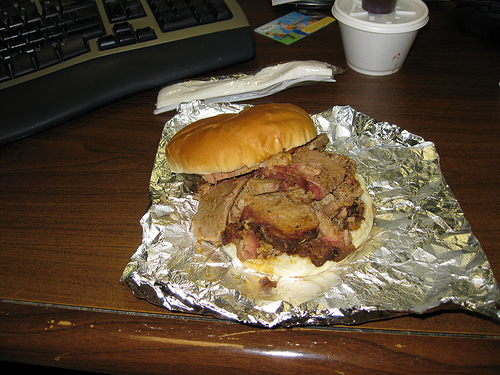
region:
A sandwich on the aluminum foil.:
[158, 108, 412, 295]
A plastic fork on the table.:
[165, 56, 360, 104]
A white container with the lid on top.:
[331, 6, 448, 75]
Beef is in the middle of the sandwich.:
[194, 168, 356, 241]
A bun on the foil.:
[153, 98, 340, 158]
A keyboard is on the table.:
[23, 11, 271, 78]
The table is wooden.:
[33, 180, 203, 362]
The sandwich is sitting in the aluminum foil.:
[168, 161, 445, 314]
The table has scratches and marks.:
[44, 313, 219, 351]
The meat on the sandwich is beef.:
[238, 180, 331, 250]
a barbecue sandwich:
[171, 120, 374, 267]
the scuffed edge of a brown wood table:
[58, 314, 235, 371]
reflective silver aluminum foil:
[394, 243, 474, 298]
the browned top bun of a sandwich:
[186, 119, 290, 152]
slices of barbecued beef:
[212, 153, 343, 249]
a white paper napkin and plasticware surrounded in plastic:
[156, 57, 336, 112]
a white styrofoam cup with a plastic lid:
[328, 1, 431, 78]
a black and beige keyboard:
[5, 4, 234, 124]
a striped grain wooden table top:
[46, 196, 107, 278]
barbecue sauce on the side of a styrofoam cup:
[380, 53, 407, 77]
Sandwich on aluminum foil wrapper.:
[119, 97, 499, 330]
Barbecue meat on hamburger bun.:
[165, 100, 378, 276]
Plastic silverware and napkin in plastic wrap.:
[150, 55, 336, 116]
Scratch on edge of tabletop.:
[113, 330, 245, 355]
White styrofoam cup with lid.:
[326, 0, 428, 75]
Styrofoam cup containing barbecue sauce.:
[327, 0, 427, 75]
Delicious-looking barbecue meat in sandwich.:
[188, 130, 364, 265]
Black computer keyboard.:
[0, 0, 250, 140]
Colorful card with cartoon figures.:
[250, 5, 335, 45]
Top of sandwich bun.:
[162, 100, 317, 175]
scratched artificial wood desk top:
[26, 302, 91, 364]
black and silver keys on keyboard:
[19, 19, 99, 101]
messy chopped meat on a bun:
[168, 112, 372, 294]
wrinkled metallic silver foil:
[369, 115, 441, 284]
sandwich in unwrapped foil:
[135, 100, 403, 284]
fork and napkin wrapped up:
[146, 51, 341, 104]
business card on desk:
[251, 3, 336, 48]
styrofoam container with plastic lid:
[328, 0, 433, 79]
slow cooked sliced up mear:
[258, 174, 323, 241]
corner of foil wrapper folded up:
[117, 252, 221, 322]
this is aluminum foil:
[116, 94, 498, 336]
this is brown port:
[232, 179, 310, 232]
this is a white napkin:
[151, 75, 334, 109]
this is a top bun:
[163, 94, 328, 173]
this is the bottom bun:
[215, 168, 380, 271]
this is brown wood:
[30, 235, 86, 285]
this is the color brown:
[37, 192, 112, 269]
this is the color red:
[245, 232, 257, 248]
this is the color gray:
[424, 218, 443, 255]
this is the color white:
[168, 91, 183, 104]